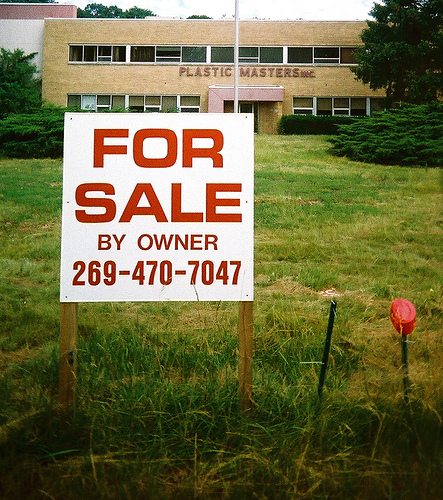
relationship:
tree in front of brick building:
[347, 0, 441, 109] [1, 2, 442, 136]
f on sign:
[94, 129, 128, 168] [60, 112, 254, 302]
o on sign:
[133, 129, 177, 168] [60, 112, 254, 302]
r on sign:
[183, 129, 223, 168] [60, 112, 254, 302]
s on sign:
[76, 183, 116, 222] [60, 112, 254, 302]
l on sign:
[172, 183, 204, 222] [60, 112, 254, 302]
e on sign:
[207, 183, 243, 223] [60, 112, 254, 302]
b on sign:
[98, 234, 112, 251] [60, 112, 254, 302]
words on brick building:
[179, 66, 316, 78] [1, 2, 442, 136]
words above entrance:
[179, 66, 316, 78] [237, 101, 255, 115]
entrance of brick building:
[237, 101, 255, 115] [1, 2, 442, 136]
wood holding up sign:
[239, 300, 253, 424] [60, 112, 254, 302]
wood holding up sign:
[60, 302, 78, 433] [60, 112, 254, 302]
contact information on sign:
[72, 261, 241, 286] [60, 112, 254, 302]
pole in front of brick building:
[232, 0, 240, 111] [1, 2, 442, 136]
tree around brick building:
[347, 0, 442, 111] [1, 2, 442, 136]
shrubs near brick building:
[0, 103, 441, 167] [1, 2, 442, 136]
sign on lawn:
[60, 112, 254, 302] [1, 133, 441, 499]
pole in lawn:
[318, 298, 337, 392] [1, 133, 441, 499]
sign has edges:
[60, 112, 254, 302] [60, 113, 255, 303]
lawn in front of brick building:
[1, 133, 441, 499] [1, 2, 442, 136]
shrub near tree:
[278, 114, 367, 135] [347, 0, 441, 109]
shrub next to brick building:
[278, 114, 367, 135] [1, 2, 442, 136]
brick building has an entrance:
[1, 2, 442, 136] [237, 101, 255, 115]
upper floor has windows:
[44, 17, 442, 97] [67, 45, 371, 70]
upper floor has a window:
[44, 17, 442, 97] [68, 45, 84, 64]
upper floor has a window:
[44, 17, 442, 97] [83, 46, 97, 62]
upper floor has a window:
[44, 17, 442, 97] [111, 47, 125, 63]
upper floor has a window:
[44, 17, 442, 97] [131, 47, 156, 64]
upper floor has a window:
[44, 17, 442, 97] [182, 47, 207, 63]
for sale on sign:
[76, 129, 242, 221] [60, 112, 254, 302]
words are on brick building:
[179, 66, 316, 78] [1, 2, 442, 136]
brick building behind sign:
[1, 2, 442, 136] [60, 112, 254, 302]